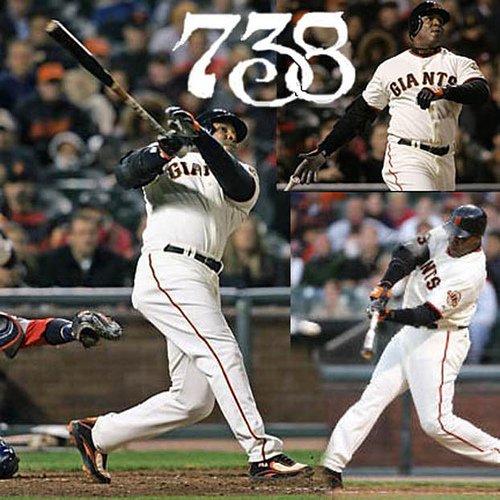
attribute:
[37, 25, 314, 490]
person — wearing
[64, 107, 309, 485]
man — swinging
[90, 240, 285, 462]
long pants — white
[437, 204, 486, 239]
helmet — black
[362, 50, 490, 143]
shirt — white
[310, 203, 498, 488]
person — swinging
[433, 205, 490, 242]
helmet — dark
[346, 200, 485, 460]
person — wearing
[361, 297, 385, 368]
bat — ready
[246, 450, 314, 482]
shoe — part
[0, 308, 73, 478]
person — wearing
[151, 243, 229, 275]
belt — black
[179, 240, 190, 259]
belt loop — white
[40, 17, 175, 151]
bat — raised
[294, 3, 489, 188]
man — wearing, black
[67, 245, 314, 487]
pant — striped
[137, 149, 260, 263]
shirt — white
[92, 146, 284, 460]
uniform — baseball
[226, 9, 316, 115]
number — part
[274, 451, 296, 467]
lace — part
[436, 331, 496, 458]
stripe — red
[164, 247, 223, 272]
belt — black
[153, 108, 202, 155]
gloves — black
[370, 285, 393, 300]
panel — orange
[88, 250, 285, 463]
pants — white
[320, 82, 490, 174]
shirt — longsleeved